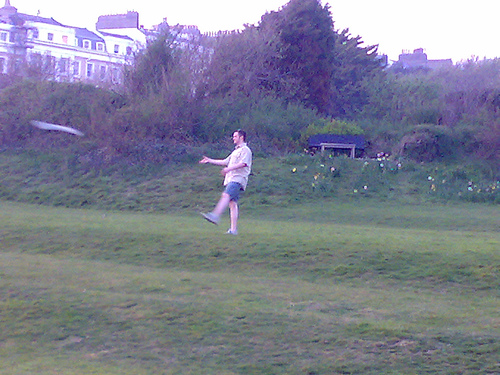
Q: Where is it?
A: This is at the field.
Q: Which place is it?
A: It is a field.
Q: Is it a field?
A: Yes, it is a field.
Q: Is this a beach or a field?
A: It is a field.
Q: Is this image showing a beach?
A: No, the picture is showing a field.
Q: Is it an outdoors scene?
A: Yes, it is outdoors.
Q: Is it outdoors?
A: Yes, it is outdoors.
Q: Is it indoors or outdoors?
A: It is outdoors.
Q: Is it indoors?
A: No, it is outdoors.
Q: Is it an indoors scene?
A: No, it is outdoors.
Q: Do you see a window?
A: Yes, there are windows.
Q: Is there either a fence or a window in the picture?
A: Yes, there are windows.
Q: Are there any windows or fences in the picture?
A: Yes, there are windows.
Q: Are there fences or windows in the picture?
A: Yes, there are windows.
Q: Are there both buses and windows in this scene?
A: No, there are windows but no buses.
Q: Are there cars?
A: No, there are no cars.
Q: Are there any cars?
A: No, there are no cars.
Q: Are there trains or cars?
A: No, there are no cars or trains.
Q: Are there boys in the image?
A: No, there are no boys.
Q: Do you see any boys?
A: No, there are no boys.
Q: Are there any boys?
A: No, there are no boys.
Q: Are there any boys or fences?
A: No, there are no boys or fences.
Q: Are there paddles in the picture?
A: No, there are no paddles.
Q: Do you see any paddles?
A: No, there are no paddles.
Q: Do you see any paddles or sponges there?
A: No, there are no paddles or sponges.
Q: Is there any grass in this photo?
A: Yes, there is grass.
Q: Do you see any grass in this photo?
A: Yes, there is grass.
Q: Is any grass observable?
A: Yes, there is grass.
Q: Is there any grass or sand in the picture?
A: Yes, there is grass.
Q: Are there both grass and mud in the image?
A: No, there is grass but no mud.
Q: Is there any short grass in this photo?
A: Yes, there is short grass.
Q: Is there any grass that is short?
A: Yes, there is grass that is short.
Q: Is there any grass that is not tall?
A: Yes, there is short grass.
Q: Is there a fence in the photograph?
A: No, there are no fences.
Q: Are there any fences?
A: No, there are no fences.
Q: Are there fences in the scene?
A: No, there are no fences.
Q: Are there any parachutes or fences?
A: No, there are no fences or parachutes.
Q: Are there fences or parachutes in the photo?
A: No, there are no fences or parachutes.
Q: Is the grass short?
A: Yes, the grass is short.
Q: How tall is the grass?
A: The grass is short.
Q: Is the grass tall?
A: No, the grass is short.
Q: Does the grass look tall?
A: No, the grass is short.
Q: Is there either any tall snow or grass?
A: No, there is grass but it is short.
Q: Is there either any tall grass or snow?
A: No, there is grass but it is short.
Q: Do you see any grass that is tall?
A: No, there is grass but it is short.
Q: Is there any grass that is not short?
A: No, there is grass but it is short.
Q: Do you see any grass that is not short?
A: No, there is grass but it is short.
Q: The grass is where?
A: The grass is in the field.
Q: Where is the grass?
A: The grass is in the field.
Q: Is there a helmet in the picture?
A: No, there are no helmets.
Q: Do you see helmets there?
A: No, there are no helmets.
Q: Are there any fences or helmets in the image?
A: No, there are no helmets or fences.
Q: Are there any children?
A: No, there are no children.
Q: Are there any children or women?
A: No, there are no children or women.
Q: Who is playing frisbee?
A: The man is playing frisbee.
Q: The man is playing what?
A: The man is playing frisbee.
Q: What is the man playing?
A: The man is playing frisbee.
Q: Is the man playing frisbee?
A: Yes, the man is playing frisbee.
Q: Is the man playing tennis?
A: No, the man is playing frisbee.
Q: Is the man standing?
A: Yes, the man is standing.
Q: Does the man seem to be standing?
A: Yes, the man is standing.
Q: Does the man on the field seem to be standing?
A: Yes, the man is standing.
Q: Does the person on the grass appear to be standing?
A: Yes, the man is standing.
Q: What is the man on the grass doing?
A: The man is standing.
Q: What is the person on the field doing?
A: The man is standing.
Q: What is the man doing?
A: The man is standing.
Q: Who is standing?
A: The man is standing.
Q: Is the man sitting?
A: No, the man is standing.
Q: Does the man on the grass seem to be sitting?
A: No, the man is standing.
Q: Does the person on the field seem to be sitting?
A: No, the man is standing.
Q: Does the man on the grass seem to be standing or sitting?
A: The man is standing.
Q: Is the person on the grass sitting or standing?
A: The man is standing.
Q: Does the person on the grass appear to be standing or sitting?
A: The man is standing.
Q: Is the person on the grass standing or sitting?
A: The man is standing.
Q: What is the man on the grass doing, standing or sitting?
A: The man is standing.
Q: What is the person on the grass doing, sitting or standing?
A: The man is standing.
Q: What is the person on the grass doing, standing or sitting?
A: The man is standing.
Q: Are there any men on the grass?
A: Yes, there is a man on the grass.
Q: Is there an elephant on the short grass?
A: No, there is a man on the grass.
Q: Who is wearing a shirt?
A: The man is wearing a shirt.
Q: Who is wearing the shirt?
A: The man is wearing a shirt.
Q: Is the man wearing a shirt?
A: Yes, the man is wearing a shirt.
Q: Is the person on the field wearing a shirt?
A: Yes, the man is wearing a shirt.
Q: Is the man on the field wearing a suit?
A: No, the man is wearing a shirt.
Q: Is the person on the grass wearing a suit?
A: No, the man is wearing a shirt.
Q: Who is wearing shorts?
A: The man is wearing shorts.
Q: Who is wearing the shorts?
A: The man is wearing shorts.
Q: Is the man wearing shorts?
A: Yes, the man is wearing shorts.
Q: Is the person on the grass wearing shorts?
A: Yes, the man is wearing shorts.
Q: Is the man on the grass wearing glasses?
A: No, the man is wearing shorts.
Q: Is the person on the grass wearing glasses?
A: No, the man is wearing shorts.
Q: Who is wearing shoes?
A: The man is wearing shoes.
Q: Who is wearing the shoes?
A: The man is wearing shoes.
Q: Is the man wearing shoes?
A: Yes, the man is wearing shoes.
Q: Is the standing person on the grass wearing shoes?
A: Yes, the man is wearing shoes.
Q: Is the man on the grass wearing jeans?
A: No, the man is wearing shoes.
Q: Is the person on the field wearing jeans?
A: No, the man is wearing shoes.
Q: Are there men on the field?
A: Yes, there is a man on the field.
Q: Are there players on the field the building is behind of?
A: No, there is a man on the field.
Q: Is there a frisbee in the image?
A: Yes, there is a frisbee.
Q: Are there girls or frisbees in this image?
A: Yes, there is a frisbee.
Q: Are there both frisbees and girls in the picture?
A: No, there is a frisbee but no girls.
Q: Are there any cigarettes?
A: No, there are no cigarettes.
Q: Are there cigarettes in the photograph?
A: No, there are no cigarettes.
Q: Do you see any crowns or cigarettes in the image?
A: No, there are no cigarettes or crowns.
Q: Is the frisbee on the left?
A: Yes, the frisbee is on the left of the image.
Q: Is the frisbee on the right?
A: No, the frisbee is on the left of the image.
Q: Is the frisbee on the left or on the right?
A: The frisbee is on the left of the image.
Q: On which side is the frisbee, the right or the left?
A: The frisbee is on the left of the image.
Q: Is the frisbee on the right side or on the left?
A: The frisbee is on the left of the image.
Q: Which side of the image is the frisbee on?
A: The frisbee is on the left of the image.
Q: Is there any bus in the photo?
A: No, there are no buses.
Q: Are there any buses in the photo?
A: No, there are no buses.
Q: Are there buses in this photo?
A: No, there are no buses.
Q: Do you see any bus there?
A: No, there are no buses.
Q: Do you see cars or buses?
A: No, there are no buses or cars.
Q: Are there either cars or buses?
A: No, there are no buses or cars.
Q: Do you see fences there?
A: No, there are no fences.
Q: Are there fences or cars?
A: No, there are no fences or cars.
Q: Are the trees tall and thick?
A: Yes, the trees are tall and thick.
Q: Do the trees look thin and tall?
A: No, the trees are tall but thick.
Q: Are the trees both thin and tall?
A: No, the trees are tall but thick.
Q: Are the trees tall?
A: Yes, the trees are tall.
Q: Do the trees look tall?
A: Yes, the trees are tall.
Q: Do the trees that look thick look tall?
A: Yes, the trees are tall.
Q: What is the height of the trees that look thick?
A: The trees are tall.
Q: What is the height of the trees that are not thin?
A: The trees are tall.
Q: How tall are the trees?
A: The trees are tall.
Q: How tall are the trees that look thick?
A: The trees are tall.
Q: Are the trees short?
A: No, the trees are tall.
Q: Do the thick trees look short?
A: No, the trees are tall.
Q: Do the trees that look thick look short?
A: No, the trees are tall.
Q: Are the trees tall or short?
A: The trees are tall.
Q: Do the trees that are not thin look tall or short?
A: The trees are tall.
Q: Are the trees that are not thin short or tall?
A: The trees are tall.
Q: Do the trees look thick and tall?
A: Yes, the trees are thick and tall.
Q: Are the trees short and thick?
A: No, the trees are thick but tall.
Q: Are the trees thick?
A: Yes, the trees are thick.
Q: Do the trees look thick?
A: Yes, the trees are thick.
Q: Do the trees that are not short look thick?
A: Yes, the trees are thick.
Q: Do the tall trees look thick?
A: Yes, the trees are thick.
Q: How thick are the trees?
A: The trees are thick.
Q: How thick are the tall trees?
A: The trees are thick.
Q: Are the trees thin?
A: No, the trees are thick.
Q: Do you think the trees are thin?
A: No, the trees are thick.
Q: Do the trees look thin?
A: No, the trees are thick.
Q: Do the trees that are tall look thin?
A: No, the trees are thick.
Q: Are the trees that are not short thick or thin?
A: The trees are thick.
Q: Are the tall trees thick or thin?
A: The trees are thick.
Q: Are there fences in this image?
A: No, there are no fences.